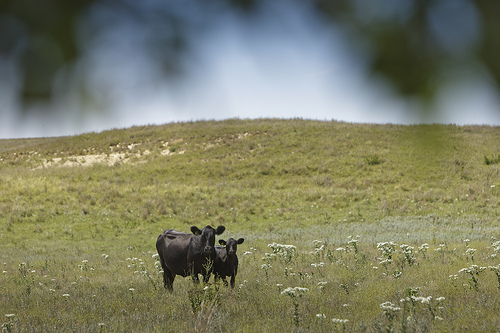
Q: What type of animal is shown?
A: Cow.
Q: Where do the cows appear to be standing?
A: Field.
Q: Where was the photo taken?
A: In a field.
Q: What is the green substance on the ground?
A: Grass.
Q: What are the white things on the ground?
A: Flowers.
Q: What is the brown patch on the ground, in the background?
A: Dirt.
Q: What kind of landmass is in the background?
A: A hill.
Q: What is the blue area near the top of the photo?
A: The sky.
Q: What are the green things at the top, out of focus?
A: Tree leaves.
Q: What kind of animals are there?
A: Cows.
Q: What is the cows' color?
A: Black.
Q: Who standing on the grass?
A: Cow.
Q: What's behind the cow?
A: Hill.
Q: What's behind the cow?
A: Brush.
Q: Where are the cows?
A: Field.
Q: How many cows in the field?
A: 2.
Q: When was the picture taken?
A: Daytime.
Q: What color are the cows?
A: Black.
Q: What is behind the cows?
A: Hills.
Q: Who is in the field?
A: Cows.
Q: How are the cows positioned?
A: Standing.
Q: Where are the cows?
A: A field.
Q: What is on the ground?
A: Grass.